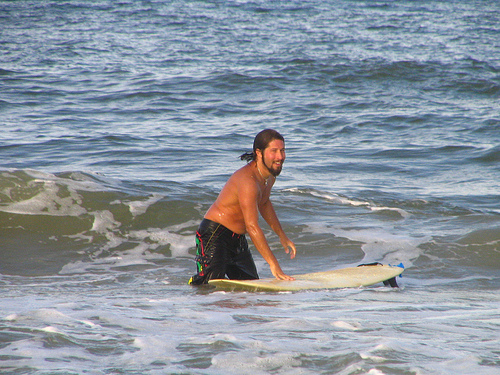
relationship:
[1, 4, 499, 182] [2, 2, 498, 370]
ripples in water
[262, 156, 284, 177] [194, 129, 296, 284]
beard on man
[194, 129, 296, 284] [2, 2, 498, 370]
man in water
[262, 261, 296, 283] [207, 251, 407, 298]
hand on surfboard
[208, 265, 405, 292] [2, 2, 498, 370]
board in water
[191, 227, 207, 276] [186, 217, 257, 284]
stripe on shorts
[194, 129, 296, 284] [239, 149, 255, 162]
man wearing ponytail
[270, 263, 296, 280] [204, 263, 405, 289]
hand on board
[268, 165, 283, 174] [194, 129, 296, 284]
beard on man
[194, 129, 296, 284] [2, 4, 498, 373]
man in ocean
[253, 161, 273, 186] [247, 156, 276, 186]
necklace on neck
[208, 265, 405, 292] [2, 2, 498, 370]
board on water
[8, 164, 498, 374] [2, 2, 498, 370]
sea foam on water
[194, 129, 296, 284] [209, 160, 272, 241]
man no shirt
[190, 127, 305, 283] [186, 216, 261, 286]
man wearing wears trunks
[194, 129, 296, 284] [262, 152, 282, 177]
man has beard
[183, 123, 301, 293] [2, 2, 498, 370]
man in water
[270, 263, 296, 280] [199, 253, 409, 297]
hand on surfboard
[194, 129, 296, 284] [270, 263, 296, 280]
man has hand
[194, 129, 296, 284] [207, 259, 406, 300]
man next surfboard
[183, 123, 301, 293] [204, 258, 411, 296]
man has surfboard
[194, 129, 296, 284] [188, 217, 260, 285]
man has shorts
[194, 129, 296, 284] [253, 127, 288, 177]
man has head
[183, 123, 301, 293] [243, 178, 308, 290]
man has arms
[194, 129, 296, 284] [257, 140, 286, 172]
man has face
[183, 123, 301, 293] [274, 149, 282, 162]
man has nose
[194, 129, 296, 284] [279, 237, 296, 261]
man has hand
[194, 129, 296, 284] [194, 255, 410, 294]
man and h surfboard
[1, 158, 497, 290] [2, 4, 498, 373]
wave in ocean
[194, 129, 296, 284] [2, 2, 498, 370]
man standing in water